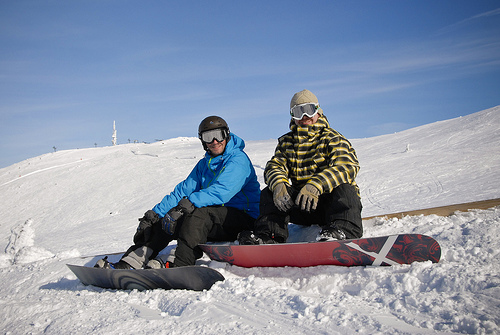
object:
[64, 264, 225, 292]
board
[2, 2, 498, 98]
blue sky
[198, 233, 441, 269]
board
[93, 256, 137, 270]
foot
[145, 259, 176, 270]
foot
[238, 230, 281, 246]
foot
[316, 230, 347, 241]
foot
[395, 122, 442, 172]
snow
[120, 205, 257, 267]
snow pants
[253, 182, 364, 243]
snow pants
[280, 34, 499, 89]
white clouds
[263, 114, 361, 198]
coat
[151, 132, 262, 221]
jacket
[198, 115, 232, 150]
helmet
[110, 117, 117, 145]
tree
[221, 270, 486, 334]
snow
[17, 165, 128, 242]
snow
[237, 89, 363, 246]
man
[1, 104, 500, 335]
hill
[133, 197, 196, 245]
gloves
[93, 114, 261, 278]
boarder